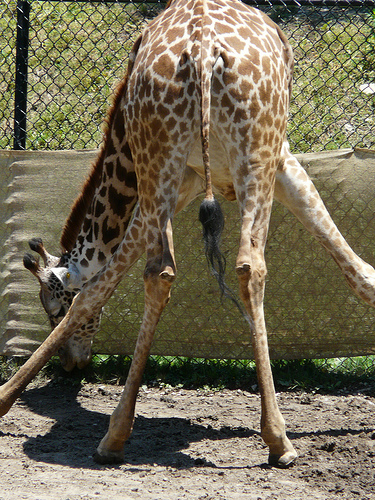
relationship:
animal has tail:
[3, 0, 375, 460] [192, 24, 245, 319]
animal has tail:
[3, 0, 375, 460] [188, 25, 233, 299]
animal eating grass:
[3, 0, 375, 460] [72, 352, 135, 378]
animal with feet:
[3, 0, 375, 460] [2, 338, 308, 476]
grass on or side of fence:
[156, 356, 259, 381] [3, 2, 362, 381]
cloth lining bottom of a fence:
[2, 143, 374, 364] [3, 2, 362, 381]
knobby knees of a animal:
[138, 239, 269, 303] [3, 0, 375, 460]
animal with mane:
[3, 0, 375, 460] [50, 55, 135, 259]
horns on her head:
[22, 251, 44, 282] [28, 244, 100, 379]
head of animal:
[28, 244, 100, 379] [3, 0, 375, 460]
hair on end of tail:
[204, 199, 253, 320] [193, 66, 254, 321]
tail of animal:
[193, 66, 254, 321] [3, 0, 375, 460]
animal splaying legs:
[3, 0, 375, 460] [0, 147, 370, 453]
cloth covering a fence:
[2, 143, 374, 364] [3, 2, 362, 381]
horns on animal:
[17, 230, 55, 277] [3, 0, 375, 460]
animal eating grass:
[3, 0, 375, 460] [2, 345, 371, 384]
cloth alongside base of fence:
[2, 143, 374, 385] [3, 2, 362, 381]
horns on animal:
[22, 251, 44, 282] [3, 0, 375, 460]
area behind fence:
[4, 7, 373, 383] [3, 2, 362, 381]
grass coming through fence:
[0, 346, 373, 391] [3, 2, 362, 381]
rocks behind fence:
[337, 71, 373, 163] [3, 2, 362, 381]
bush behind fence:
[348, 20, 373, 84] [3, 2, 362, 381]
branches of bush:
[355, 15, 374, 68] [348, 20, 373, 84]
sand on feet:
[4, 378, 370, 499] [267, 447, 298, 471]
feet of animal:
[267, 447, 298, 471] [3, 0, 375, 460]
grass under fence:
[91, 353, 373, 394] [3, 2, 362, 381]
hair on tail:
[197, 201, 254, 326] [188, 32, 256, 327]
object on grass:
[327, 357, 347, 369] [89, 352, 374, 399]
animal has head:
[3, 0, 375, 460] [22, 234, 102, 379]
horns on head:
[21, 234, 60, 283] [22, 234, 102, 379]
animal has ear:
[3, 0, 375, 460] [49, 265, 82, 290]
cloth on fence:
[2, 143, 374, 364] [3, 2, 362, 381]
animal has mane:
[3, 0, 375, 460] [58, 74, 126, 249]